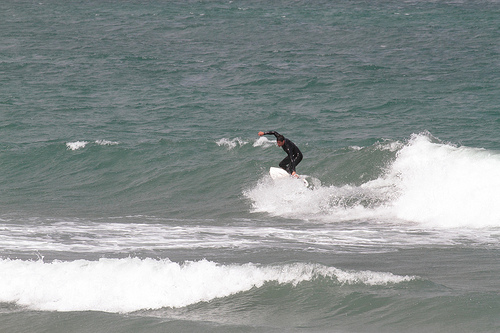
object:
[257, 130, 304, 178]
man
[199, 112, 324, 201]
sport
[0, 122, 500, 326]
waves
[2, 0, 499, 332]
ocean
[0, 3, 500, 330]
ripples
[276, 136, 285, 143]
hair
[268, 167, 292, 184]
surfboard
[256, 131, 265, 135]
hand